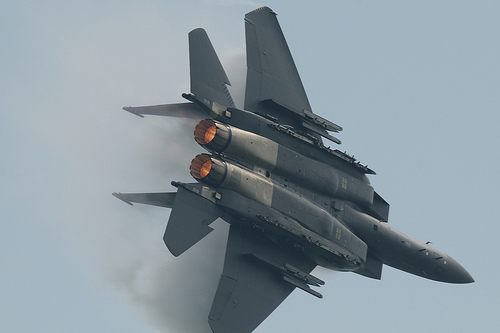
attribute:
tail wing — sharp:
[162, 180, 224, 258]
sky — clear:
[334, 9, 491, 139]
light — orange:
[185, 118, 220, 178]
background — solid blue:
[24, 23, 115, 317]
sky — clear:
[17, 15, 136, 188]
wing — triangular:
[241, 8, 323, 147]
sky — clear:
[19, 40, 98, 291]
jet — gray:
[113, 3, 475, 330]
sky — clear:
[29, 34, 166, 153]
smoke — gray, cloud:
[124, 110, 292, 331]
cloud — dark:
[122, 126, 202, 180]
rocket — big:
[116, 10, 473, 331]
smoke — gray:
[93, 32, 210, 328]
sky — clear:
[347, 25, 460, 113]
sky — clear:
[2, 0, 482, 327]